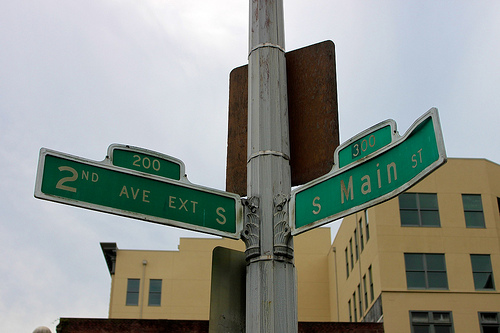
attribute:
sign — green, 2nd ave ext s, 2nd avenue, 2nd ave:
[35, 138, 237, 240]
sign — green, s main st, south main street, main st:
[288, 102, 445, 222]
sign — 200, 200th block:
[108, 140, 183, 180]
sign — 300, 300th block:
[334, 111, 394, 160]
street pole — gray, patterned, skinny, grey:
[249, 4, 296, 332]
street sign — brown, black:
[226, 38, 349, 199]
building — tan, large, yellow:
[108, 138, 500, 332]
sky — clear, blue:
[4, 4, 498, 332]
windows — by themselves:
[125, 268, 164, 309]